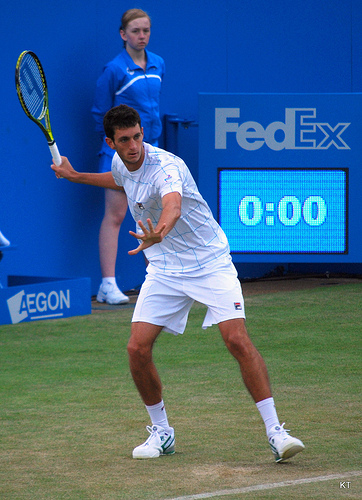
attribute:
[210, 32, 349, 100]
wall — bright blue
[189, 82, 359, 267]
sign — blue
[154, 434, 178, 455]
stripes — green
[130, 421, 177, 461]
sneakers — white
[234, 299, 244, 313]
logo — white, red, blue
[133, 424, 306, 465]
shoes — white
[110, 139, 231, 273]
shirt — white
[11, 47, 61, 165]
racket — yellow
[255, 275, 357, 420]
grass — scorched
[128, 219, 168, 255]
fingers — outstretched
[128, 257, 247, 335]
shorts — white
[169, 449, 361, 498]
line — white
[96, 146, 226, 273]
shirt — white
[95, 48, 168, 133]
jacket — blue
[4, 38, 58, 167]
racket — gold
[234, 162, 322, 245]
clock — large 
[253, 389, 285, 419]
sock — white, long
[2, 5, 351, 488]
tennis court — grass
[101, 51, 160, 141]
blue jacket — blue 